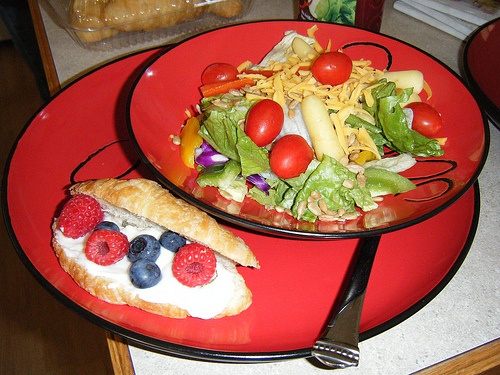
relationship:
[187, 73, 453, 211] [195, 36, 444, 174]
lettuce in salad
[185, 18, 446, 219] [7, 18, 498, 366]
salad in plate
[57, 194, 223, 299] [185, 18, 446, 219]
raspberry in salad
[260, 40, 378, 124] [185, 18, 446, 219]
cheese in salad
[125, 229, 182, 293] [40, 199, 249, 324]
blueberry on bread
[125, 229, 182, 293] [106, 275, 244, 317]
blueberry on top of cream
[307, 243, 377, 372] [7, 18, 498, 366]
metal utensil under plate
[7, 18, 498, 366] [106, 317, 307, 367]
plate have black trim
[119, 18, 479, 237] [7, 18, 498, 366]
bowl have plate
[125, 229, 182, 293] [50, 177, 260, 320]
blueberry inside bread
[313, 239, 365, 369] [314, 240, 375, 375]
part of a handle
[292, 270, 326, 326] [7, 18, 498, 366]
part of a plate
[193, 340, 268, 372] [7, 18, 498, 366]
edge of a plate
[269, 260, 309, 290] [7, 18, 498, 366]
part of a plate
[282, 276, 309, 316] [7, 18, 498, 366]
part of a plate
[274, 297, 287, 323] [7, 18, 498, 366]
part of a plate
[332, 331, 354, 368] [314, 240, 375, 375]
part of a handle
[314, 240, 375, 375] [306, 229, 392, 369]
handle of a utensil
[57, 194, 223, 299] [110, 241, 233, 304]
raspberry on cream cheese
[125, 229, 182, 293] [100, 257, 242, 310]
blueberry on cream cheese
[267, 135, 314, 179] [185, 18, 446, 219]
cherry tomato in a salad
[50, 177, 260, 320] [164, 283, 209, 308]
bread with cream